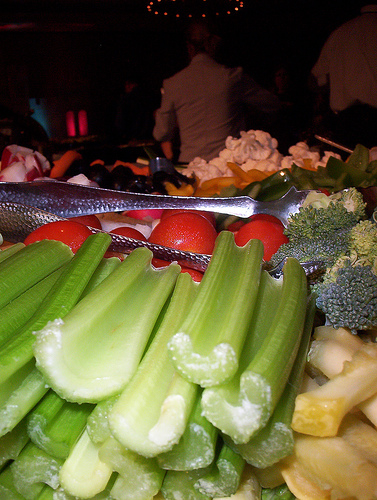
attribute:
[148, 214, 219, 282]
tomato — small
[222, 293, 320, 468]
celery — green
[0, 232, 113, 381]
celery — green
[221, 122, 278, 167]
cauliflower — white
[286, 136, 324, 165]
cauliflower — white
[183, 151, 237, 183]
cauliflower — white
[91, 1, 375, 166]
group — partygoers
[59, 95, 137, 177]
shaded lamp — red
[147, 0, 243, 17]
light fixture — circular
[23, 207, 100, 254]
tomato — bright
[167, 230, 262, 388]
celery — green, cut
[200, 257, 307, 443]
celery — green, cut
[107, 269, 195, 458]
celery — green, cut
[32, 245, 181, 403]
celery — green, cut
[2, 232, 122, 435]
celery — green, cut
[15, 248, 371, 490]
celery — cut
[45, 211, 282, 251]
tomatoes — cherry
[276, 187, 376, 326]
broccoli — small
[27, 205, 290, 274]
tomatos — cherry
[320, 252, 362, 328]
broccoli — small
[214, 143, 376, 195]
peppers — sliced, fresh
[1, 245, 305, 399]
celery — cut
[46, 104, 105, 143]
light — red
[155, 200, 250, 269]
cherry tomato — bright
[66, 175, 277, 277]
cherry tomatos — small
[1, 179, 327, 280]
tong — silver, small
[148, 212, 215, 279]
tomato — ripe, juicy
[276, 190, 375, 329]
head — broccoli